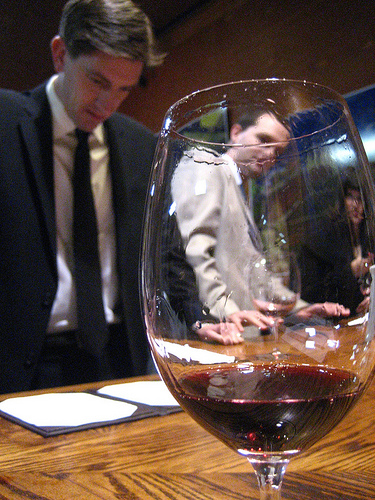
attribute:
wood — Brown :
[13, 423, 242, 496]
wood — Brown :
[295, 448, 373, 485]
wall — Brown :
[139, 0, 374, 147]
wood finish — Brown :
[3, 413, 234, 498]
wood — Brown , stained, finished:
[0, 317, 374, 499]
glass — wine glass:
[136, 72, 364, 491]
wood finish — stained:
[39, 446, 156, 499]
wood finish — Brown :
[3, 310, 374, 499]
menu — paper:
[14, 371, 251, 465]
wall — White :
[139, 17, 351, 119]